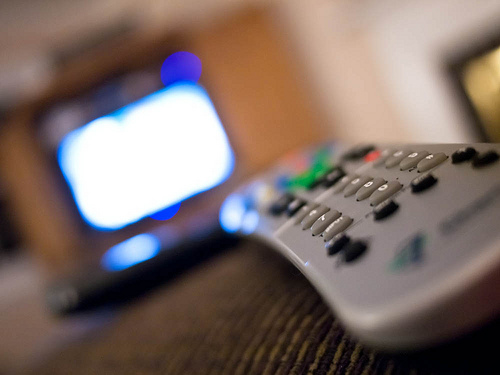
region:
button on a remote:
[322, 216, 359, 244]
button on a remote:
[367, 181, 401, 209]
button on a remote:
[416, 146, 453, 184]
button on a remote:
[355, 178, 385, 210]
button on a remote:
[379, 198, 399, 230]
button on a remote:
[323, 238, 350, 255]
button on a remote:
[437, 141, 481, 165]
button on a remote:
[406, 171, 433, 196]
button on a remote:
[465, 152, 499, 170]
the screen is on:
[70, 87, 248, 210]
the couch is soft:
[255, 333, 355, 364]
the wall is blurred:
[5, 177, 108, 272]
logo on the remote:
[429, 195, 499, 226]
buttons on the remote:
[249, 135, 452, 210]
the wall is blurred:
[309, 32, 422, 104]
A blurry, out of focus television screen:
[55, 82, 232, 234]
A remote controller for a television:
[221, 139, 498, 351]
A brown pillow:
[22, 236, 497, 373]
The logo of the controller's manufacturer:
[388, 232, 430, 272]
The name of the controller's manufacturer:
[432, 182, 498, 241]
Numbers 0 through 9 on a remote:
[293, 145, 445, 242]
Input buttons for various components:
[324, 145, 498, 268]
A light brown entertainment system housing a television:
[2, 2, 332, 282]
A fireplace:
[450, 28, 497, 149]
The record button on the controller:
[365, 150, 380, 162]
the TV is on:
[66, 73, 238, 240]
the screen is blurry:
[62, 70, 224, 237]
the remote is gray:
[229, 98, 461, 260]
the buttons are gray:
[305, 141, 438, 233]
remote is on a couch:
[144, 127, 443, 359]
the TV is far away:
[52, 79, 242, 269]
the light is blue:
[60, 80, 224, 231]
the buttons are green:
[292, 158, 329, 185]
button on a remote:
[337, 226, 378, 274]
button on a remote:
[363, 185, 401, 233]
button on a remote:
[409, 172, 444, 193]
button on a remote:
[323, 208, 351, 238]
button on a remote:
[359, 169, 413, 204]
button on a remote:
[410, 143, 445, 173]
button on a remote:
[293, 201, 330, 228]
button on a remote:
[330, 166, 381, 210]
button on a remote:
[459, 152, 494, 170]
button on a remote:
[270, 176, 297, 217]